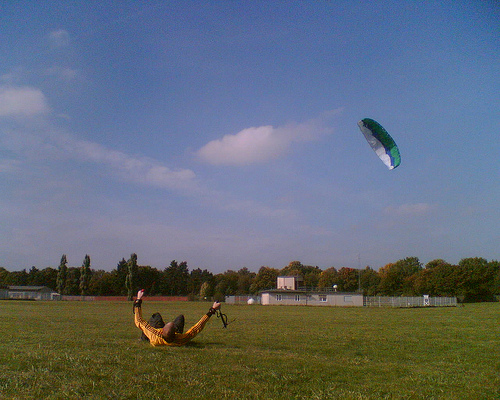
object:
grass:
[0, 298, 499, 399]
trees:
[0, 253, 500, 302]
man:
[132, 290, 220, 347]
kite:
[357, 117, 401, 171]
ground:
[0, 299, 500, 400]